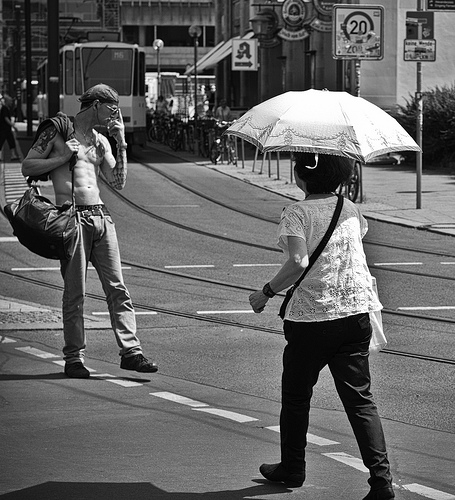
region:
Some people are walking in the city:
[33, 30, 423, 493]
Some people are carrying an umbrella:
[31, 73, 415, 458]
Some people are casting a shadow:
[26, 56, 448, 493]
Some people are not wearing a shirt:
[26, 48, 422, 492]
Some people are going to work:
[26, 52, 429, 489]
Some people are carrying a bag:
[7, 40, 449, 495]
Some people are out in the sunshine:
[8, 47, 452, 497]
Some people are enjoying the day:
[14, 60, 451, 496]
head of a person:
[73, 69, 132, 135]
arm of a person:
[22, 137, 74, 192]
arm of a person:
[94, 145, 152, 191]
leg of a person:
[50, 254, 94, 347]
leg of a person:
[87, 228, 170, 352]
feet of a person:
[61, 358, 94, 374]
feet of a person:
[103, 349, 158, 388]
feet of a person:
[250, 450, 321, 495]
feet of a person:
[359, 470, 408, 496]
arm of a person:
[250, 247, 309, 315]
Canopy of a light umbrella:
[226, 88, 425, 164]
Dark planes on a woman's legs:
[280, 314, 393, 487]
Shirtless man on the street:
[14, 84, 159, 379]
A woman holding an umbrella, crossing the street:
[227, 88, 423, 491]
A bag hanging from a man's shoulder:
[3, 118, 79, 258]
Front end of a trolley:
[66, 45, 145, 144]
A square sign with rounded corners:
[333, 5, 383, 61]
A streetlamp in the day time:
[187, 26, 201, 119]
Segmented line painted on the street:
[4, 329, 451, 498]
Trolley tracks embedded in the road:
[141, 166, 270, 258]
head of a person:
[284, 143, 347, 200]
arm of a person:
[232, 241, 321, 322]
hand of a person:
[245, 275, 282, 314]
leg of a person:
[256, 327, 343, 459]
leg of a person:
[317, 345, 396, 459]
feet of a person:
[248, 459, 315, 483]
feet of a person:
[363, 471, 402, 498]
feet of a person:
[57, 363, 99, 386]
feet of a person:
[111, 351, 169, 378]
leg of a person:
[51, 263, 97, 343]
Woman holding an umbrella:
[221, 80, 424, 496]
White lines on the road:
[0, 162, 449, 494]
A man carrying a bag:
[0, 82, 130, 259]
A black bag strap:
[275, 191, 341, 316]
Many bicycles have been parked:
[143, 99, 237, 164]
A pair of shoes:
[55, 347, 160, 378]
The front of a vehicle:
[53, 35, 148, 139]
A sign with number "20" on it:
[325, 0, 382, 65]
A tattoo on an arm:
[22, 118, 61, 161]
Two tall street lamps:
[147, 19, 203, 120]